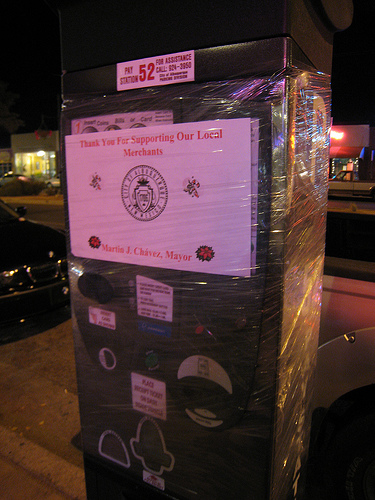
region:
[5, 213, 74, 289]
this is a car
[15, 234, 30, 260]
the car is black in color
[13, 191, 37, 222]
this is the side mirror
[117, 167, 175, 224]
this is a berge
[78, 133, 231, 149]
this is a writing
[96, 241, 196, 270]
the writing is red in color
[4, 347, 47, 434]
this is the road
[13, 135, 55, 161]
this is a building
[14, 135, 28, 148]
the wall is white in color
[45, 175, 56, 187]
the car is white in color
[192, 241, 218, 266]
small picture on a sign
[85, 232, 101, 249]
small picture on a sign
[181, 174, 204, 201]
small picture on a sign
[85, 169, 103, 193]
small picture on a sign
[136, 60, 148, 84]
red letter on a sign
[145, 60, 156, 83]
red letter on a sign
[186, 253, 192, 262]
red letter on a sign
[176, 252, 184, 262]
red letter on a sign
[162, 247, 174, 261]
red letter on a sign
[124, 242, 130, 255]
red letter on a sign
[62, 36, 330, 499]
The dark package full of stickers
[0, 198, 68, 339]
The dark car on the left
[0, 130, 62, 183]
The buildings on the left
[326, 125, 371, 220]
The buildings on the right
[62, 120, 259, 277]
The white sticker with printed mayor's name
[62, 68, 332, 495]
The clear wrapping polythene paper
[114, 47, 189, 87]
The top sticker with a printed number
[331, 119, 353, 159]
The glowing red light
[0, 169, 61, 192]
The cars parked outside the block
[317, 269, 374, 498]
The partially blocked white car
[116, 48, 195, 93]
parking meter label saying that this is pay station 52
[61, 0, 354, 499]
parking meter station that is all wrapped in plastic wrap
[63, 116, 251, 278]
white sign on the meter pay station that say 'thank you for supporting our local merchants - martin chavez, mayor'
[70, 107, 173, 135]
sign underneath the plastic wrap and white sign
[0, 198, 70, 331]
shiny black newer british motor works vehicle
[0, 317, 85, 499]
dirty concrete from years of traffic and wear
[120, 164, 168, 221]
symbol of the city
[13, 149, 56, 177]
store front with its lights on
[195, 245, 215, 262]
christmas poinsettia plant drawing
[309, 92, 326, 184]
yellow letter P for parking on the pay station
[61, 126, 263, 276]
White sign on unit.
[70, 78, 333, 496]
Plastic wrap around unit.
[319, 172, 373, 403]
Silver car beside unit.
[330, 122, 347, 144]
Red neon lights on the building.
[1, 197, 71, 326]
Black car parked on the street.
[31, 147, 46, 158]
Light on the building.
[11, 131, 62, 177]
Store front of building.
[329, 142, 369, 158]
Red awning front of building.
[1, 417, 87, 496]
White line on the road.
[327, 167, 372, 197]
Red and white truck parked on street.